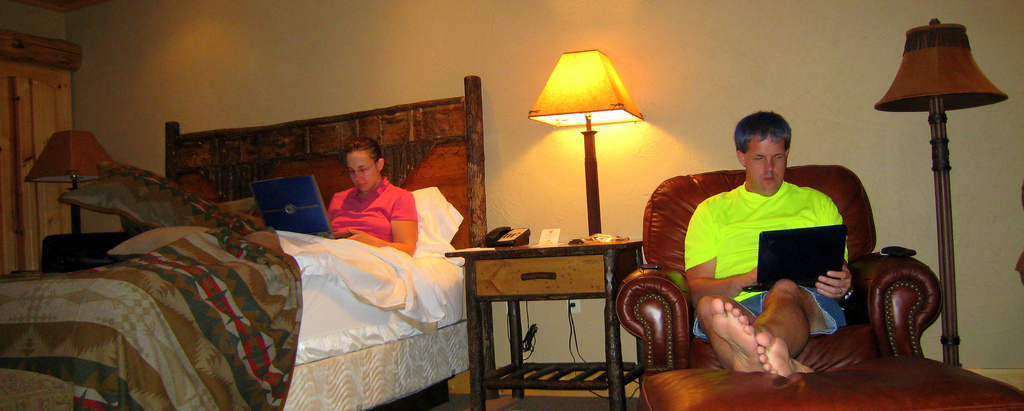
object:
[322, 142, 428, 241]
woman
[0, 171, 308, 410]
blanket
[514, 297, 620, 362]
cord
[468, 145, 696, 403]
wall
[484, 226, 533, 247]
phone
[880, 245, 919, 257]
remote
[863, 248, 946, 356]
arm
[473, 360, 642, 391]
rack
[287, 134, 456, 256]
man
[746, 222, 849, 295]
laptop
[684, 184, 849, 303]
shirt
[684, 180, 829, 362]
shirt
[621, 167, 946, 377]
chair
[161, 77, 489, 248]
head board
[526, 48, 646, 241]
lamp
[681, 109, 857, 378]
man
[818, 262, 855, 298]
hand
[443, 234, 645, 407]
side table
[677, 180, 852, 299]
shirt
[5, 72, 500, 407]
bed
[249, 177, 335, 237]
laptop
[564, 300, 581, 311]
wall outlet